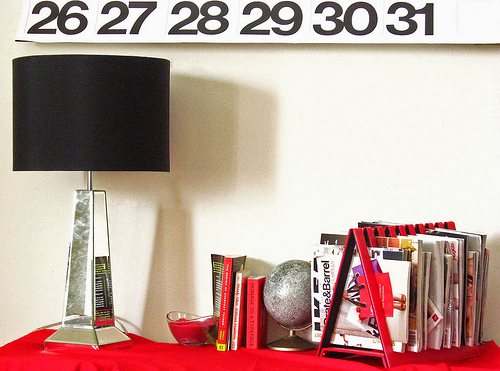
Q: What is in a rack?
A: Magizines.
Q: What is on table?
A: Cloth.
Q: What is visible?
A: A calendar.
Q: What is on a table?
A: A lamp.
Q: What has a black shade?
A: A lamp.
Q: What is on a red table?
A: A lamp.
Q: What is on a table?
A: Books.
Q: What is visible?
A: Books.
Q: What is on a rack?
A: Magazines.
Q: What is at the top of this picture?
A: Numbers.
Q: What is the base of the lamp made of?
A: Glass mirror.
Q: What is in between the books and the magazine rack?
A: A globe.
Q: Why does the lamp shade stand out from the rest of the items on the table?
A: The lamp shade is a different color.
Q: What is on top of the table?
A: A red tablecloth.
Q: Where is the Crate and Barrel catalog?
A: In the magazine rack.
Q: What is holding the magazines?
A: A magazine rack.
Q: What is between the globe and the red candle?
A: Three books.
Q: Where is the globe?
A: Between the magazine rack and the books.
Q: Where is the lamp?
A: On the left side of the table.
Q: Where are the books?
A: On a table.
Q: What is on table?
A: Lamps and books.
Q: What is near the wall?
A: Lamp, books an magazines.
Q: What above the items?
A: Black numbers.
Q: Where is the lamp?
A: On the table.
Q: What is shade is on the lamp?
A: Black lamp shade.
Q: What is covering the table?
A: Red cloth.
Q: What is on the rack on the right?
A: A display of magazines.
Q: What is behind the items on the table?
A: A wall.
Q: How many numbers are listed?
A: 6.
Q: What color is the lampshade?
A: Black.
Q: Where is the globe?
A: To the right of the books.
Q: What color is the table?
A: Red.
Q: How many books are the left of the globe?
A: 3.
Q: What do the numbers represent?
A: The final days of the month.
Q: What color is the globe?
A: Silver.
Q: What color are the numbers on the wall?
A: Black.